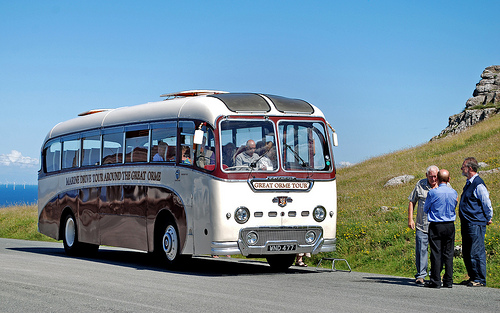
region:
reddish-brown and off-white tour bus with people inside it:
[33, 89, 341, 270]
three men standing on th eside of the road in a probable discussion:
[406, 156, 493, 289]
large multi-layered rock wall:
[429, 65, 497, 140]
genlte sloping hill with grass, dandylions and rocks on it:
[3, 112, 496, 282]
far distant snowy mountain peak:
[1, 148, 40, 168]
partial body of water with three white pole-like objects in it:
[1, 181, 38, 208]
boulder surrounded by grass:
[383, 173, 415, 188]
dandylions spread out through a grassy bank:
[340, 221, 417, 251]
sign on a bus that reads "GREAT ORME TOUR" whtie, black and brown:
[246, 177, 314, 193]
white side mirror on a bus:
[191, 121, 207, 146]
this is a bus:
[27, 102, 354, 277]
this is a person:
[401, 148, 448, 285]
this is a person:
[422, 168, 462, 289]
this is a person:
[455, 145, 497, 309]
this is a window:
[171, 121, 206, 165]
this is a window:
[80, 129, 105, 166]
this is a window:
[221, 126, 272, 170]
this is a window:
[268, 108, 326, 175]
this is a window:
[44, 138, 59, 175]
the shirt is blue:
[424, 188, 459, 220]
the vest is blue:
[456, 183, 488, 221]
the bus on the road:
[37, 89, 337, 266]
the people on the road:
[408, 157, 493, 287]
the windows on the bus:
[44, 119, 331, 172]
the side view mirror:
[193, 120, 203, 142]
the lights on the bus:
[226, 206, 333, 244]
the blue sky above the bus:
[0, 0, 497, 184]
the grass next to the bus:
[0, 111, 498, 286]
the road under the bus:
[0, 237, 498, 312]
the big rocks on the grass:
[377, 160, 498, 210]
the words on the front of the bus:
[251, 182, 308, 189]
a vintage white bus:
[34, 92, 346, 263]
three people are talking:
[396, 144, 498, 294]